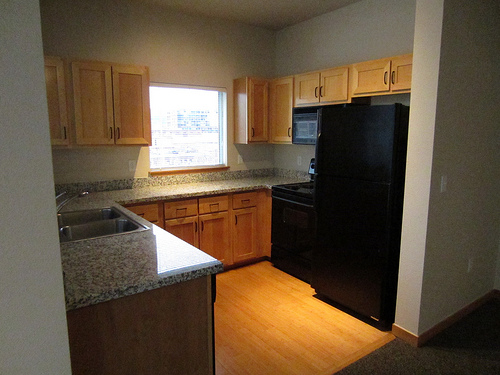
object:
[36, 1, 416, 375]
kitchen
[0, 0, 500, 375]
house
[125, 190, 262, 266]
cabinets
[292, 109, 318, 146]
microwave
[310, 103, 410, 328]
refrigerator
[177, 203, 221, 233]
handles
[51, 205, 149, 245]
sink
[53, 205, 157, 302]
counter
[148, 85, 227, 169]
window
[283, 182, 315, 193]
stove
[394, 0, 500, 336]
wall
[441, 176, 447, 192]
switch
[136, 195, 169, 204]
granite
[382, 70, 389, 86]
knobs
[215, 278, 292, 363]
tile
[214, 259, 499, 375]
floor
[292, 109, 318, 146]
oven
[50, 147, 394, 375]
ktichen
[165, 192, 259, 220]
drawers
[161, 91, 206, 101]
light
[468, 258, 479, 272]
plug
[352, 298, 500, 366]
hallway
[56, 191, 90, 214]
faucet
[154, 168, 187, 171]
sunlight